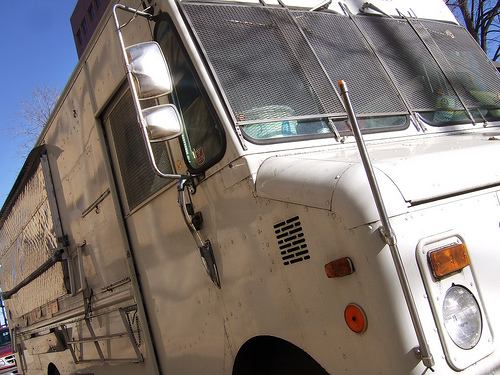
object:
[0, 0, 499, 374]
van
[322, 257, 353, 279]
signal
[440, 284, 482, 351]
headlight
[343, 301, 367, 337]
reflector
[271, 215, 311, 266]
vent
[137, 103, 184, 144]
rear view mirror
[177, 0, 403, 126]
windshield protector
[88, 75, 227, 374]
door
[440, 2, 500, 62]
tree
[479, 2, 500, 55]
branch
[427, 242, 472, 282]
light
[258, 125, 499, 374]
front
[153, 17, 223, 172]
window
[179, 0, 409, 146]
windshield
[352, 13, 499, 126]
windshield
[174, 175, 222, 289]
handel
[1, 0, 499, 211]
sky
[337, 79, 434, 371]
pole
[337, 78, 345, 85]
tip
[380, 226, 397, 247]
brackets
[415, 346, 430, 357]
brackets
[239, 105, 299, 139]
bucket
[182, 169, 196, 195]
bracket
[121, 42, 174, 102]
mirrors